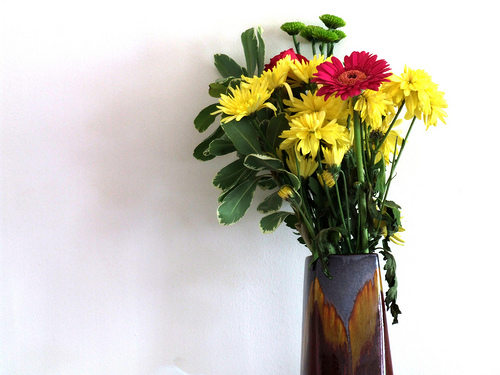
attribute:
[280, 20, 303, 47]
flower — green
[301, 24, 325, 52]
flower — green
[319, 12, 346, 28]
flower — green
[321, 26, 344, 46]
flower — green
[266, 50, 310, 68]
flower — red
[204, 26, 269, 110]
leaves — large, green, white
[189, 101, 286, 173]
leaves — large, green, white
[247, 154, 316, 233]
leaves — large, green, white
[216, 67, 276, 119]
flower — yellow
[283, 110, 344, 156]
flower — yellow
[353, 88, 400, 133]
flower — yellow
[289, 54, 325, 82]
flower — yellow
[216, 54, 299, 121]
yellow flower — yellow 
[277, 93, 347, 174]
yellow flower — yellow 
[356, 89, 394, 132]
yellow flower — yellow 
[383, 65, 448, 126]
yellow flower — yellow 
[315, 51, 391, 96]
flower — red 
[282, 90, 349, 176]
flower — yellow 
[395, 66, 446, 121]
flower — yellow 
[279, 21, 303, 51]
flower — green 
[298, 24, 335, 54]
flower — green 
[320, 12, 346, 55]
flower — green 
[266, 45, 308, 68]
flower — red 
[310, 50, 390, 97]
flower — red 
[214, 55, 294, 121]
flower — yellow 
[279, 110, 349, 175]
flower — yellow  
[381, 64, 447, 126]
flower — yellow  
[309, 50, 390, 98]
daisy — dark pink  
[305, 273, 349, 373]
flower petal — burgundy, yellow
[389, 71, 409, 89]
petals — yellow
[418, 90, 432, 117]
petals — yellow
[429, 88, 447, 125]
petals — yellow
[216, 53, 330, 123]
daisies — yellow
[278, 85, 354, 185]
daisies — yellow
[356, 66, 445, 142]
daisies — yellow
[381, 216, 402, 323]
leaf — whittled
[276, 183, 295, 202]
flowers — yellow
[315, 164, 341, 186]
flowers — yellow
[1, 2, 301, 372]
wall — white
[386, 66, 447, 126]
flower — yellow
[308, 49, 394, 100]
flower — pink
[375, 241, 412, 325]
leaf — dead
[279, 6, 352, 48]
flowers — green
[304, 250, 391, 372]
vase — ceramic, dark brown , light brown,  ceramic,  grey, orange, and red,  orange and red, w/ brown color, w/ purple  color, w/ blue   color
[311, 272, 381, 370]
design —  V,  vase's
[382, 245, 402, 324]
leaves —  flower's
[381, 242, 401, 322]
leaves —   wilting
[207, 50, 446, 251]
flowers —  yellow and pink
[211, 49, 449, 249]
daisies —  yellow and pink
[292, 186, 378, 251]
stems —  flowers'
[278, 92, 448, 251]
flowers —  yellow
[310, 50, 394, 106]
flowers —  pink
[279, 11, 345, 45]
flowers —  green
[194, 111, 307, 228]
leaves —  flower's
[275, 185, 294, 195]
flower —  not fully grown